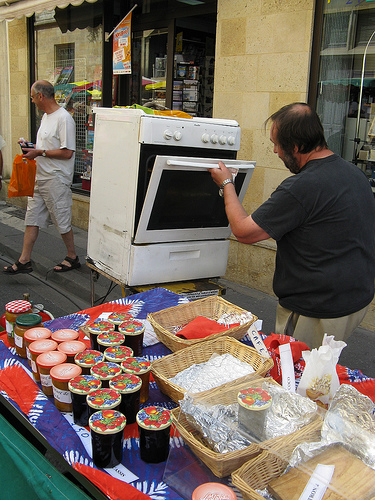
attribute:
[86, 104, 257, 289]
oven — old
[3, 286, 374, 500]
table cloth — red, blue, tie-dyed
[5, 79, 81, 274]
person — walking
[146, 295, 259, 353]
basket — wicker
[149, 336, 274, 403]
basket — wicker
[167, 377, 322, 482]
basket — wicker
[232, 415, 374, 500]
basket — wicker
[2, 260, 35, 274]
sandal — brown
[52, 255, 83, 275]
sandal — brown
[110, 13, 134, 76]
banner — advertising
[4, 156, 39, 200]
bag — orange, plastic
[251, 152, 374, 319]
shirt — black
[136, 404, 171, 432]
lid — decorative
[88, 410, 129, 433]
lid — decorative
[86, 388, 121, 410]
lid — decorative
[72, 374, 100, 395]
lid — decorative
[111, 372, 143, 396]
lid — decorative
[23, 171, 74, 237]
pants — beige